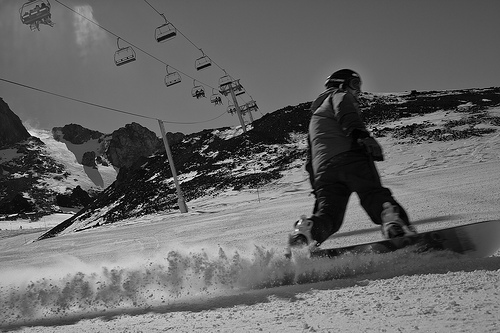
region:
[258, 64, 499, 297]
person snowboarding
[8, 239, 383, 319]
snow being pulled up by the back of the snowboard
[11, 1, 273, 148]
ski lift carrying people to the slopes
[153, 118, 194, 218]
pole supporting the ski lift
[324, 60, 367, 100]
black helmet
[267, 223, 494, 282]
snowboard tilted sideways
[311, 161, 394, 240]
black snow pants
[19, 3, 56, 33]
ski lift cart carrying people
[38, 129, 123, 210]
snow laying on the mountain side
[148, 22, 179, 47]
empty ski lift car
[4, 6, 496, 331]
Black and white filter.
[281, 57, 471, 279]
Person is snow boarding.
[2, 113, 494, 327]
Snow covering the ground.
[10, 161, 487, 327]
The snow is white.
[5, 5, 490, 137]
The sky is clear.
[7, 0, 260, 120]
The chairlift is grey.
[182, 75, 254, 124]
People on the chair lift.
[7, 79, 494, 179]
Snow covering the hills.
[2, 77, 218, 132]
The wires are black.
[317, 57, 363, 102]
Person is wearing a helmet.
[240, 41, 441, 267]
the guy wears jacket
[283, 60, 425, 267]
a man skiiing across the snow.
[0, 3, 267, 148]
a ski lift over snow.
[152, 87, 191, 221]
a ski lift support.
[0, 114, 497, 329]
a snow covered field.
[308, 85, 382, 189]
a man in a puffy jacket.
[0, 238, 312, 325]
tracks left in the snow from a skier.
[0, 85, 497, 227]
a snow covered hillside.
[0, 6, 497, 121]
a clear sky above a ski lift.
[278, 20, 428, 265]
a man dressed in winter attire.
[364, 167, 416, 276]
the left leg of a man.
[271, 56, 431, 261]
Skier on a hill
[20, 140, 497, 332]
Field cover with snow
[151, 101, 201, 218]
Electrical pole on side of ski track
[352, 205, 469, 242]
Shadow of person cast on snow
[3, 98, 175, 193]
Mountains cover with snow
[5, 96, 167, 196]
Mountains are rocky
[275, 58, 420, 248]
Snowboarder wears helmet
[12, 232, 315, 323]
Snow raised by snowboard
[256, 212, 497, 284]
Snowboard is gray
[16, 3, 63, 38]
People